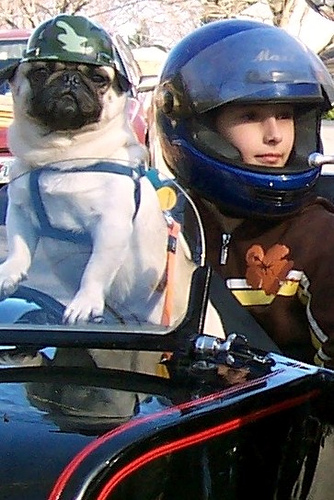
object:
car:
[0, 26, 154, 181]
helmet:
[152, 18, 332, 219]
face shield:
[171, 23, 334, 121]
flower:
[246, 243, 294, 296]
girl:
[154, 20, 334, 385]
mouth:
[254, 152, 283, 165]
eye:
[242, 112, 259, 121]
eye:
[277, 110, 291, 120]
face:
[216, 102, 296, 166]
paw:
[63, 293, 105, 325]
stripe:
[47, 366, 325, 499]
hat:
[0, 13, 142, 94]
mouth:
[48, 86, 83, 121]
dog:
[0, 10, 226, 342]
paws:
[0, 264, 26, 295]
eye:
[92, 73, 105, 83]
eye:
[35, 67, 49, 73]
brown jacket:
[171, 189, 333, 371]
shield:
[181, 25, 333, 114]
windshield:
[0, 144, 207, 333]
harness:
[29, 161, 145, 242]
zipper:
[220, 233, 231, 264]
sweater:
[170, 182, 334, 373]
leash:
[162, 220, 182, 326]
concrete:
[305, 432, 334, 500]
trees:
[2, 0, 326, 27]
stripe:
[225, 271, 329, 370]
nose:
[62, 71, 80, 86]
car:
[0, 167, 334, 500]